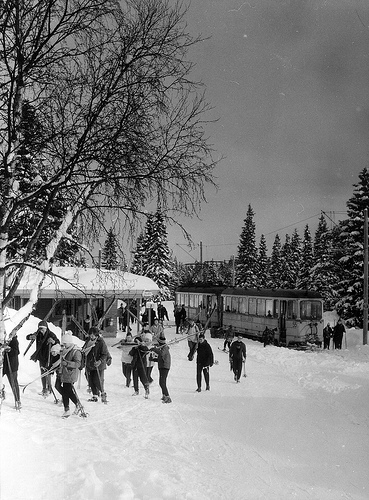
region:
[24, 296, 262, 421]
people carrying skiis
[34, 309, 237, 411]
people walking in snow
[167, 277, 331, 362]
black and white train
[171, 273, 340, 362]
train in the snow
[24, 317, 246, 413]
black and white crowd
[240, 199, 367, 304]
black and white trees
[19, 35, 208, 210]
tree with no leaves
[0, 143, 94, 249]
white snow on branches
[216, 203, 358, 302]
white snow on pine trees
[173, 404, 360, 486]
snow on the ground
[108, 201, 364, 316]
Lots of pine trees and snow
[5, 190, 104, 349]
Snow sticking to the tree branches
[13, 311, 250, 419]
People lining up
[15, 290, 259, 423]
People carrying their ski equipment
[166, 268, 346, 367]
Old style trolley train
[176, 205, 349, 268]
Cables supported by poles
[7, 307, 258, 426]
Bundled up for cold weather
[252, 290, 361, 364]
Watching from a distance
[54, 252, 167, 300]
Snow on the roof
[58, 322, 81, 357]
White ski hat with pom pom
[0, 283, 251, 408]
a group of people with skis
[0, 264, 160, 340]
a house with snow on the roof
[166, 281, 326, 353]
a train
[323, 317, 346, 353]
two people standing by the train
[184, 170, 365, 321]
big trees in the background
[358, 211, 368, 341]
an electricity pole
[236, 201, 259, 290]
a tall tree behind the train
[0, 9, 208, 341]
a big tree with no leaves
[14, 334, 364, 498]
a lot of snow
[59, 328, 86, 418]
a lady with a white hat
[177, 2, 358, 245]
the clear sky above everything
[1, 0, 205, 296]
a tall leafless tree next to the building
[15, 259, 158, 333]
the building next to everything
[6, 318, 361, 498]
the snow on the ground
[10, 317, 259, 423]
the people walking up the hill to ski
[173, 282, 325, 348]
the train next to the building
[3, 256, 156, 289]
the snow on top of the building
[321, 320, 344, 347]
people standing next to the train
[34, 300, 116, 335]
the building the skiiers got their skis at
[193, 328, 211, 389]
a man walking in the snow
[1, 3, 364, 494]
A black and white image of a snowy day.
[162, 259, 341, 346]
A train in a black and whie image.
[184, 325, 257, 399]
Two people near each other.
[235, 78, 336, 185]
The sky is gray in this image.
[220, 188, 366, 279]
Trees covered in snow.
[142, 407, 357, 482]
Snow on the ground.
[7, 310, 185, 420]
People carrying skies.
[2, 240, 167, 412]
A building behind the people.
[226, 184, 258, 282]
A pine tree in a black and white image.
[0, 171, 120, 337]
Snow on the trunk of a tree.